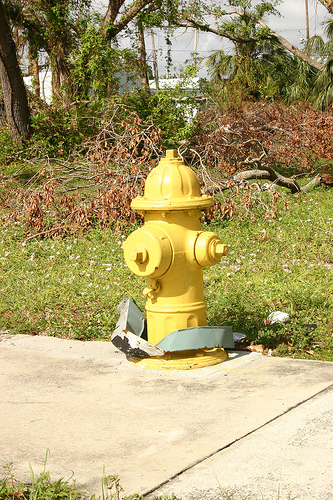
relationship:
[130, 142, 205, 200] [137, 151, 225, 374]
top of fire hydrant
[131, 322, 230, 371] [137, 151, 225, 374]
base of fire hydrant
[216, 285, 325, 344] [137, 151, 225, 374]
shadow from fire hydrant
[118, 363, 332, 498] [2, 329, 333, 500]
cracks in pavement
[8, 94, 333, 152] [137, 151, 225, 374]
bushes behind fire hydrant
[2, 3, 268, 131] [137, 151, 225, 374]
trees behind fire hydrant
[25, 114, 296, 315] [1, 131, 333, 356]
debris on grass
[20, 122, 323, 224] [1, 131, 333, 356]
branch on grass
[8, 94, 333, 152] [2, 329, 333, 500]
bushes near pavement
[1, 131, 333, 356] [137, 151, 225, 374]
grass behind fire hydrant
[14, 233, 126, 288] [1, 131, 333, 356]
flowers in grass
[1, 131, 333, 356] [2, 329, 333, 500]
grass on side of pavement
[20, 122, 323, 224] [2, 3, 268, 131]
branch from trees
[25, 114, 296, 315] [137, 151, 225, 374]
debris near fire hydrant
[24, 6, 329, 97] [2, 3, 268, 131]
leaves on trees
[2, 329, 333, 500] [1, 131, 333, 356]
pavement near grass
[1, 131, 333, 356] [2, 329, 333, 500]
grass by pavement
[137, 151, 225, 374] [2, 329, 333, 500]
fire hydrant mounted on pavement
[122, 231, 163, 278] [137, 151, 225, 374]
nozzle on fire hydrant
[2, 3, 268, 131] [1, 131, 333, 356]
trees among grass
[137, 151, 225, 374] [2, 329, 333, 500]
fire hydrant on pavement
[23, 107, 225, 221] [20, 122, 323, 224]
leaves on branch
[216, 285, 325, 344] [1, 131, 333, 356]
shadow on grass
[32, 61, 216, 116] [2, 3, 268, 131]
building behind trees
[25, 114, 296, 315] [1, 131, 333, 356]
debris in grass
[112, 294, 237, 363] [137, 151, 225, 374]
scrap metal around fire hydrant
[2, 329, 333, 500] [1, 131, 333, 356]
pavement surrounded by grass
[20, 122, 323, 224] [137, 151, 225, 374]
branch behind fire hydrant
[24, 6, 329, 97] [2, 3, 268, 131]
poles behind trees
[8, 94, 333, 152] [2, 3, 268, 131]
bushes around trees